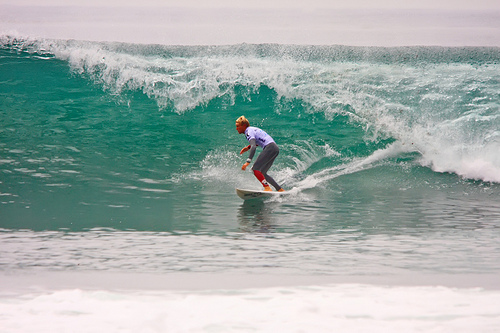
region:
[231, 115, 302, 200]
A man surfs the waves.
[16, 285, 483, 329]
The ocean waves crash in front.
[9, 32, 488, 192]
The surfer rides the long wave.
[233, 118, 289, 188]
The surfer wears surf gear.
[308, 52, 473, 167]
Bubbles and foam follow the wave.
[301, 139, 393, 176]
The wave left by the surfer.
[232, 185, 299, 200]
The white surf board.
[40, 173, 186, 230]
The ocean water looks green.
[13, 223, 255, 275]
The calm bubbles on the water.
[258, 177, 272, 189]
The surfer wears a cord for the board.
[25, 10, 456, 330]
A person is in the ocean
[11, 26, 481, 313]
A person is on a surfboard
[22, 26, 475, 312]
A person is doing some surfing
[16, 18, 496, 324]
A person is close to the beach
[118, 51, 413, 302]
A person is getting some exercise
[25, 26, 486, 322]
A person is on an ocean wave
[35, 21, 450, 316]
A person is on their vacation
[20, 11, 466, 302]
A person is taking a day off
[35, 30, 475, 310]
A person is out in the sunshine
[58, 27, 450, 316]
A person is enjoying the day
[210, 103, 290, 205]
a guy riding on a surfboard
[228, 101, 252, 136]
the head of a surfer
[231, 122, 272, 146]
the shirt of a surfer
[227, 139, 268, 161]
the arms of a surfer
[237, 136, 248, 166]
the hands of a surfer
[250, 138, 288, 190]
the grey pants of a surfer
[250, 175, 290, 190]
the bare feet of a surfer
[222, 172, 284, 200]
a long white board for surfing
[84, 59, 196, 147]
a giant wave in the ocean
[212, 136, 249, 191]
the mist of a wave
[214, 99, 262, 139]
face of the girl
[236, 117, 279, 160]
a man wearing shirt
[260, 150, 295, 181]
a man wearing pant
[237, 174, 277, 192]
a man wearing safety pad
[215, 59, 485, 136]
a flow of water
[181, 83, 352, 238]
a man inside the water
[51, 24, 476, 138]
an ocean wave breaking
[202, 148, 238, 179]
a spray of water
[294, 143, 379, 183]
a small wake in the water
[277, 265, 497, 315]
a group of bubbles in the water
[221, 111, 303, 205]
a surfer riding a wave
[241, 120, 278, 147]
a light purple rashguard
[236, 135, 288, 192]
a grey wetsuit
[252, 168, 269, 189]
a patch of bright red cloth